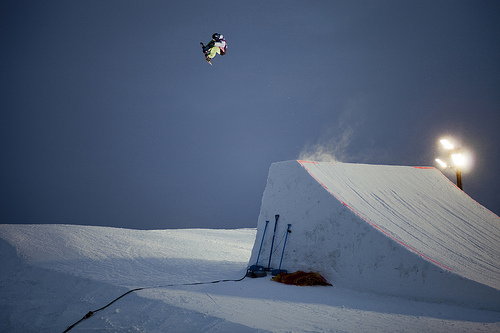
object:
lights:
[430, 128, 478, 175]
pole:
[452, 169, 467, 191]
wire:
[199, 278, 243, 296]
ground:
[89, 252, 121, 267]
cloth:
[276, 264, 337, 288]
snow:
[332, 169, 480, 237]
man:
[204, 29, 232, 60]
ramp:
[374, 180, 479, 267]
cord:
[119, 285, 182, 301]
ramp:
[235, 273, 265, 317]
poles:
[277, 213, 296, 273]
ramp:
[303, 285, 337, 302]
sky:
[354, 32, 419, 47]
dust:
[305, 104, 364, 164]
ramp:
[355, 139, 378, 167]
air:
[102, 127, 152, 142]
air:
[112, 81, 159, 89]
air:
[114, 20, 170, 35]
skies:
[225, 39, 254, 56]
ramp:
[313, 234, 361, 262]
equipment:
[247, 211, 315, 274]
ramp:
[321, 162, 370, 257]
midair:
[188, 77, 239, 101]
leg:
[200, 47, 220, 60]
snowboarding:
[193, 26, 219, 55]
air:
[285, 22, 319, 31]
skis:
[196, 42, 217, 66]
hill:
[249, 164, 500, 313]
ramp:
[352, 207, 374, 237]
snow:
[364, 204, 396, 264]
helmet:
[211, 33, 224, 38]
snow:
[387, 249, 422, 279]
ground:
[210, 299, 242, 311]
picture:
[225, 106, 449, 282]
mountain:
[2, 213, 176, 265]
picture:
[34, 24, 143, 191]